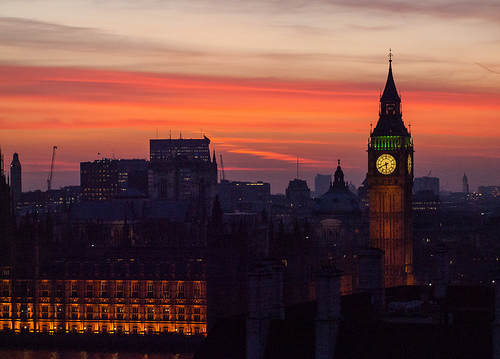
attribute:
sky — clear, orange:
[2, 0, 484, 217]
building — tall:
[356, 43, 417, 288]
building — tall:
[360, 43, 415, 293]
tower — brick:
[347, 42, 426, 291]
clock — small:
[365, 150, 402, 181]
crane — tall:
[42, 134, 63, 191]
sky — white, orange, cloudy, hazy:
[2, 3, 499, 203]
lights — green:
[368, 127, 414, 153]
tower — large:
[354, 40, 426, 294]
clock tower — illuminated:
[341, 44, 431, 328]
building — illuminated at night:
[0, 46, 427, 356]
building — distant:
[140, 123, 235, 214]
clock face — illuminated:
[362, 141, 410, 184]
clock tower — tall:
[352, 33, 420, 324]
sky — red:
[5, 14, 497, 223]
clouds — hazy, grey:
[27, 0, 486, 92]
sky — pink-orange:
[20, 3, 480, 181]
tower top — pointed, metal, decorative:
[362, 26, 413, 85]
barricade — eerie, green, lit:
[360, 124, 425, 160]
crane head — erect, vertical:
[35, 130, 64, 203]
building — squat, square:
[57, 149, 187, 211]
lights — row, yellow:
[242, 172, 282, 199]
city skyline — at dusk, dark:
[63, 127, 403, 232]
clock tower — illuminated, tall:
[352, 43, 428, 317]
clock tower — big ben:
[337, 22, 438, 310]